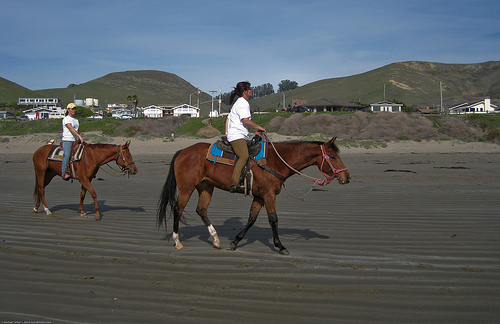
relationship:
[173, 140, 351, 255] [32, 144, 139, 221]
horse near horse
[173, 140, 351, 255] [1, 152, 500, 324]
horse on beach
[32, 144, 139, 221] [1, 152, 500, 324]
horse on beach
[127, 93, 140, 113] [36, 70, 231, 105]
tree on hill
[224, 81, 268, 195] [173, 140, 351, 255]
woman riding horse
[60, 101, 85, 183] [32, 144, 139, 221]
woman riding horse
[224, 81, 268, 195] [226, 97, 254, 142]
woman wearing shirt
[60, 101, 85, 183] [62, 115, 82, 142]
woman wearing shirt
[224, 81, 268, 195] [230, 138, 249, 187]
woman wearing pants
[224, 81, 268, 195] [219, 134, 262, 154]
woman on saddle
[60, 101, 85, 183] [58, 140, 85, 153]
woman on saddle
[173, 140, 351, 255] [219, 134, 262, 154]
horse wearing saddle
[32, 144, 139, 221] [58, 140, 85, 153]
horse wearing saddle